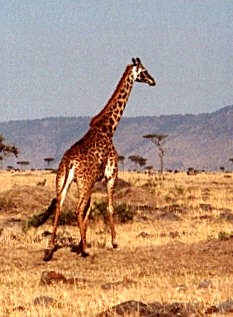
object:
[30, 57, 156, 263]
giraffe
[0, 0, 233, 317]
wild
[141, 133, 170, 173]
tree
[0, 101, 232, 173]
hills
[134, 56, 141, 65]
knobs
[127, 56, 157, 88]
head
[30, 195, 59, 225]
hair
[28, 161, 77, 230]
tail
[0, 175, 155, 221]
dirt mounds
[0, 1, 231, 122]
sky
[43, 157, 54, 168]
tree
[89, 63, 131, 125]
mane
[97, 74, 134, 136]
neck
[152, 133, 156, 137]
leaves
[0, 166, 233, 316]
plants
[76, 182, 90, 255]
legs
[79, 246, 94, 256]
feet